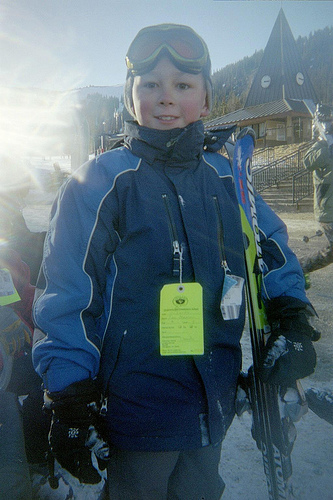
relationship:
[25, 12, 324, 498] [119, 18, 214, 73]
boy wears goggles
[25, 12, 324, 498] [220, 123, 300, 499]
boy hold skis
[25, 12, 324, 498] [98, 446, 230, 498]
boy wears blue jeans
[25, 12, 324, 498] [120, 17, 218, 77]
boy wears hat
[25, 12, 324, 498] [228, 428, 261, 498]
boy on snow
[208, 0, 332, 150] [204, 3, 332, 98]
ski lodge on background